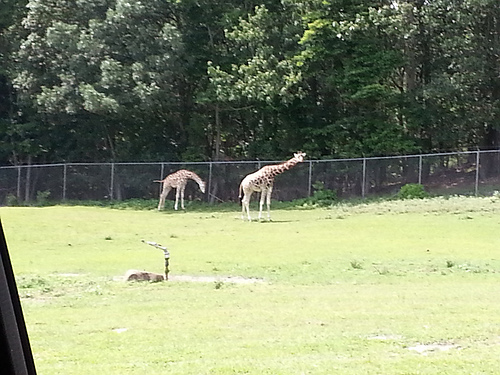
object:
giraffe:
[238, 147, 308, 223]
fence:
[1, 146, 500, 209]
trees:
[49, 0, 136, 202]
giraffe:
[153, 169, 211, 211]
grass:
[0, 195, 497, 369]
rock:
[126, 269, 165, 282]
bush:
[393, 182, 429, 199]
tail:
[153, 178, 163, 184]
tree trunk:
[115, 183, 124, 202]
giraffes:
[239, 149, 307, 224]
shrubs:
[101, 196, 177, 210]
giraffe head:
[198, 182, 208, 193]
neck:
[271, 158, 295, 176]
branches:
[385, 65, 413, 94]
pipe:
[140, 238, 170, 280]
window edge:
[0, 216, 39, 375]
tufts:
[346, 258, 364, 271]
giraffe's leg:
[244, 187, 253, 218]